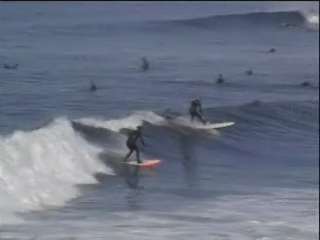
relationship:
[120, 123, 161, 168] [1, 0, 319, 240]
surfer in ocean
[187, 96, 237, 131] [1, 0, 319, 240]
surfer in ocean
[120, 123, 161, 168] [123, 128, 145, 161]
surfer wearing suit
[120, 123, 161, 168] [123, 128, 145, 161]
surfer bending forward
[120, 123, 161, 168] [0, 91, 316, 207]
surfer on wave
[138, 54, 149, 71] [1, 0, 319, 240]
person in sea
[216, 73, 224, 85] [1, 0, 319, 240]
person in sea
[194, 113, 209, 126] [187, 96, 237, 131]
leg of surfer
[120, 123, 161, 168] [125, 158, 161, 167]
surfer on surfboard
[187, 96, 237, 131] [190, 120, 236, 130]
surfer on surfboard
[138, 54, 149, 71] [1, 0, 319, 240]
person in ocean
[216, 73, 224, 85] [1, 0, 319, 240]
person in ocean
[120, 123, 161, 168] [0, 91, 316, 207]
surfer riding wave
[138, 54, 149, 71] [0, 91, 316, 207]
person waiting for wave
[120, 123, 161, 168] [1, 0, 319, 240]
surfer surfing in ocean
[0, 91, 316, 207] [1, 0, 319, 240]
wave in ocean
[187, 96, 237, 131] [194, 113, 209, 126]
surfer has leg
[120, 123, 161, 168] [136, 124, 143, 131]
surfer has a head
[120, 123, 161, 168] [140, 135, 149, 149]
surfer has a arm